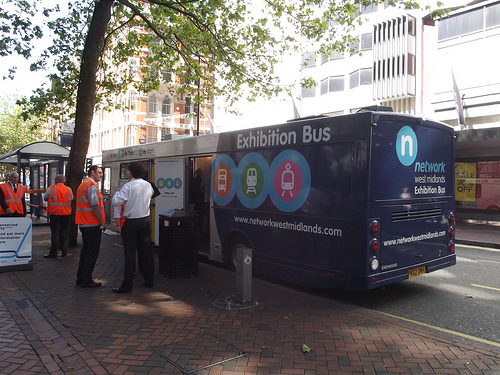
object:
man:
[73, 165, 105, 287]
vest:
[71, 176, 104, 227]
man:
[46, 175, 72, 259]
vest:
[49, 184, 73, 215]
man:
[0, 176, 30, 266]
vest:
[0, 180, 27, 212]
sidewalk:
[2, 208, 499, 370]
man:
[116, 166, 157, 294]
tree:
[55, 3, 114, 250]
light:
[368, 222, 380, 235]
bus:
[99, 112, 455, 297]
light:
[370, 239, 382, 249]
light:
[369, 259, 380, 270]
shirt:
[114, 176, 157, 219]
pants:
[123, 221, 154, 290]